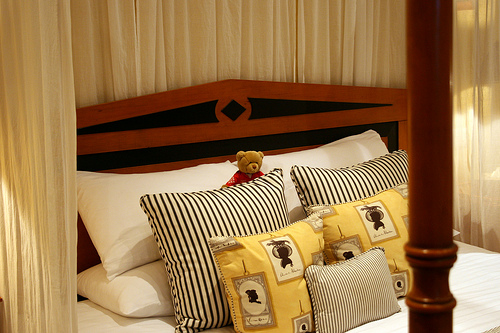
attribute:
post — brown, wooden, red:
[401, 1, 458, 331]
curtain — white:
[0, 0, 495, 333]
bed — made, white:
[73, 73, 499, 331]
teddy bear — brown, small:
[218, 149, 275, 190]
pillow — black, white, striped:
[135, 170, 288, 327]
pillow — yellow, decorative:
[210, 210, 323, 331]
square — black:
[218, 98, 246, 125]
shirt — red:
[226, 172, 265, 186]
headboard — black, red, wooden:
[73, 76, 414, 171]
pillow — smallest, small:
[303, 245, 401, 331]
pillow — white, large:
[76, 155, 256, 252]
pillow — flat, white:
[76, 257, 199, 325]